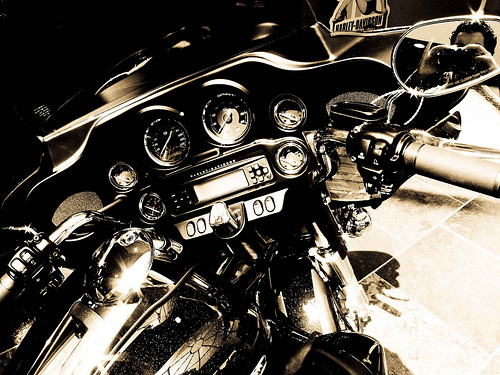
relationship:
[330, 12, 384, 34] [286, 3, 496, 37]
company logo on background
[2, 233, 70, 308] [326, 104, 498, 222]
handle on handlebars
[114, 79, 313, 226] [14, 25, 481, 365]
control panel front motorcycle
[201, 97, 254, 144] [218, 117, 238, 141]
circle with hands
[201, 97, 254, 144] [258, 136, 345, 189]
circle on circle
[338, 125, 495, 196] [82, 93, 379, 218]
handlebar sticking out of control panel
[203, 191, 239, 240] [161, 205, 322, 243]
metal knob in middle of buttons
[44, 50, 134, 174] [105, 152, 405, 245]
curved outer edge of control panel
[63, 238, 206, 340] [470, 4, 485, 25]
attachment reflecting sparkle of light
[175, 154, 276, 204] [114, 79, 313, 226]
radio in middle of control panel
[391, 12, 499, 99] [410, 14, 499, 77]
rear view mirror showing man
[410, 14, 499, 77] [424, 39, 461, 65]
man holding binoculars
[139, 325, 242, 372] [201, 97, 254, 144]
spokes around circle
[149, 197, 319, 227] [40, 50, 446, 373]
braking gear of motorcycle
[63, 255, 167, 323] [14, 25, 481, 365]
gas cap of motorcycle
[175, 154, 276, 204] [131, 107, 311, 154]
radio below speedometer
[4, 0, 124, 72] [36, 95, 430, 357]
background behind bike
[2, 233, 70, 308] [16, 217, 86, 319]
handle with brake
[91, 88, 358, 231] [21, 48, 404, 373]
dials of bike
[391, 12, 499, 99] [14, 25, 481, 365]
rear view mirror of motorcycle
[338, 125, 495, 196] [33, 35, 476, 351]
handlebar on bike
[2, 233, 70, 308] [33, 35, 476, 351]
handle on bike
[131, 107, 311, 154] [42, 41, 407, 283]
speedometer on bike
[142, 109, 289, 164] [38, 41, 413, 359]
gauge on bike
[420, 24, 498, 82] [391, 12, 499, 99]
man taking picture in rear view mirror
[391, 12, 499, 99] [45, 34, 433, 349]
rear view mirror of bike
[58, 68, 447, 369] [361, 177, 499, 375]
bike parked on ceramic floor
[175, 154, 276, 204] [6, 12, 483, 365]
radio on bike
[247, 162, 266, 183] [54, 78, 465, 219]
buttons on handle.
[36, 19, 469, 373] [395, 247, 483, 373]
motorcycle parked ground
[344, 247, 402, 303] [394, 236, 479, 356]
shadows cast on ground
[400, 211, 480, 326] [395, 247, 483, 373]
concrete on ground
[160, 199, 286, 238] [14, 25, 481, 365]
buttons on motorcycle